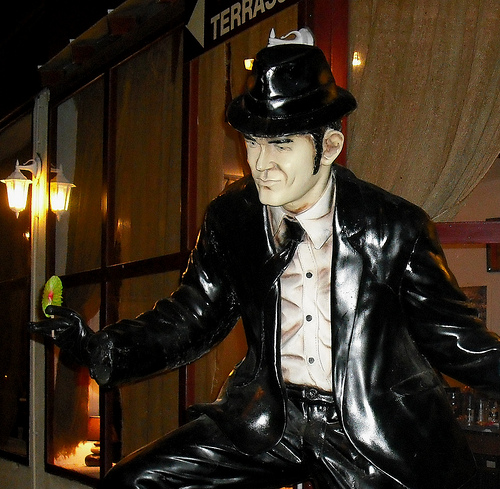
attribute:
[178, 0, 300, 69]
sign — black, white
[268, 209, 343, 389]
shirt — tan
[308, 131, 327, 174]
hair — black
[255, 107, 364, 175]
hair — black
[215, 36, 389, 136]
hat — black, shiny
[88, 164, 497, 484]
coat — black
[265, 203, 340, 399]
shirt — white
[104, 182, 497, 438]
jacket — black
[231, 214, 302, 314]
tie — black